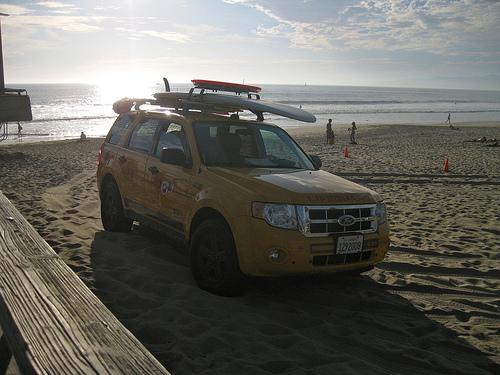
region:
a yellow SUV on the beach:
[90, 110, 392, 285]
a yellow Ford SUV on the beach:
[95, 110, 389, 290]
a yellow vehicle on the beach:
[96, 80, 388, 292]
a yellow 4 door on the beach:
[92, 110, 389, 290]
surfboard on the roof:
[139, 77, 319, 129]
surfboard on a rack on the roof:
[149, 76, 325, 122]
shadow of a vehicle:
[90, 223, 499, 373]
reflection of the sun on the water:
[91, 82, 152, 145]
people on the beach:
[319, 109, 367, 149]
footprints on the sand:
[40, 179, 95, 285]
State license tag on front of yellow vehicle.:
[318, 226, 381, 267]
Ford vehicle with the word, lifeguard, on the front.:
[110, 122, 390, 292]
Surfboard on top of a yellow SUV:
[102, 85, 330, 173]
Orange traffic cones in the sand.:
[335, 143, 460, 173]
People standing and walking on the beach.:
[312, 105, 465, 146]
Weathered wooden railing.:
[0, 208, 162, 373]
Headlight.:
[246, 189, 303, 246]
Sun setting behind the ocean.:
[14, 45, 448, 122]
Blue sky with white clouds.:
[0, 0, 499, 70]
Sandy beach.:
[405, 175, 479, 357]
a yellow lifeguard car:
[97, 91, 413, 295]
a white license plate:
[326, 228, 377, 263]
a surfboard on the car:
[112, 66, 337, 132]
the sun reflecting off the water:
[72, 40, 177, 119]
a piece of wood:
[0, 187, 170, 374]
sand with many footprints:
[369, 127, 498, 262]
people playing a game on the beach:
[312, 106, 387, 167]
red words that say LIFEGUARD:
[294, 190, 383, 207]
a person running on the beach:
[437, 103, 465, 138]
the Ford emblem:
[332, 213, 364, 229]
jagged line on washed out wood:
[32, 270, 94, 358]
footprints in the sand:
[34, 190, 99, 238]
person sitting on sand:
[62, 120, 94, 147]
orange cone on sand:
[343, 142, 357, 164]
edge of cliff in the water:
[5, 76, 40, 125]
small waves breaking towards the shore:
[345, 98, 440, 113]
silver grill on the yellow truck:
[285, 198, 406, 259]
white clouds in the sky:
[273, 8, 454, 59]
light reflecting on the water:
[70, 33, 156, 91]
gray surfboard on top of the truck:
[142, 60, 322, 127]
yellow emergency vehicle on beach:
[89, 89, 423, 313]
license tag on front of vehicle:
[324, 224, 381, 263]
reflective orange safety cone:
[332, 142, 361, 173]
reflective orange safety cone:
[428, 150, 462, 188]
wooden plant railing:
[2, 179, 121, 372]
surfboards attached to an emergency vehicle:
[150, 67, 340, 134]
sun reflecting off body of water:
[58, 72, 178, 140]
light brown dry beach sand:
[400, 184, 495, 328]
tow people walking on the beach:
[309, 112, 374, 147]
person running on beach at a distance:
[439, 106, 459, 124]